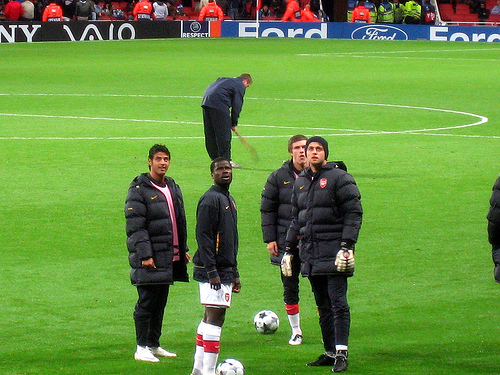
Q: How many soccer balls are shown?
A: Two.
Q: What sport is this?
A: Soccer.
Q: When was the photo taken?
A: Before the match.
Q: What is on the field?
A: Grass.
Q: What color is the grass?
A: Green.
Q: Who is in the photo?
A: The players.